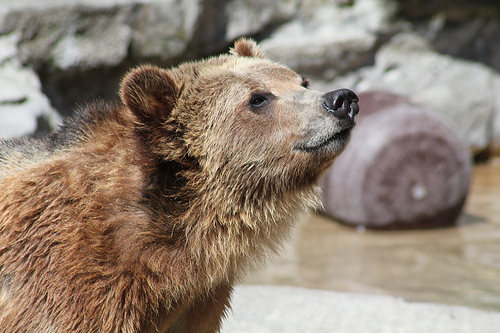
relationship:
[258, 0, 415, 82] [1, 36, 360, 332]
rock behind bear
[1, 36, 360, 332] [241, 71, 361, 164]
bear has face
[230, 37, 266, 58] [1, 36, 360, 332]
ear on top of bear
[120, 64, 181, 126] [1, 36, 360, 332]
right ear on top of bear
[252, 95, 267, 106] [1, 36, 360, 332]
eye on front of bear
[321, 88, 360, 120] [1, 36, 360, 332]
nose on front of bear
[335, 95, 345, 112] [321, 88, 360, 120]
nostril on front of nose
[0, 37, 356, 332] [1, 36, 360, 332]
fur on surface of bear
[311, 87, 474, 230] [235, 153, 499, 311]
barrel in middle of water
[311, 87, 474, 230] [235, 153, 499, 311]
barrel floating in water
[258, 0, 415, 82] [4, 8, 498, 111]
rock on background